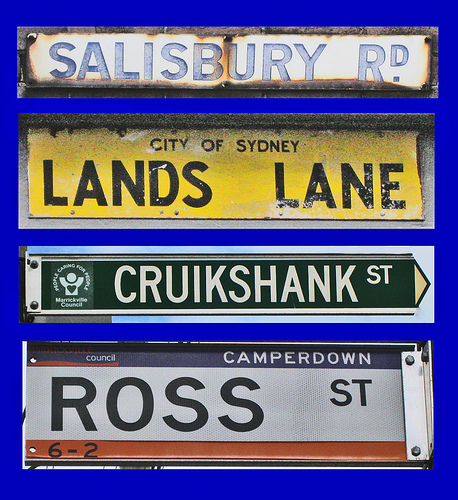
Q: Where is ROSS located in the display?
A: At the bottom.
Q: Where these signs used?
A: To indicate street name.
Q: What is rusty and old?
A: The sign.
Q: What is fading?
A: The lettering.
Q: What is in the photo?
A: Street signs.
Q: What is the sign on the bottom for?
A: Ross st.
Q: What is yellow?
A: The lands lane sign.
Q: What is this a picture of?
A: Street signs.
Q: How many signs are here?
A: 4.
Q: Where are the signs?
A: In the picture.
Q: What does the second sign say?
A: LANDS LANE.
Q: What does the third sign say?
A: CRUIKSHANK.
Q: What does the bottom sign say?
A: ROSS.